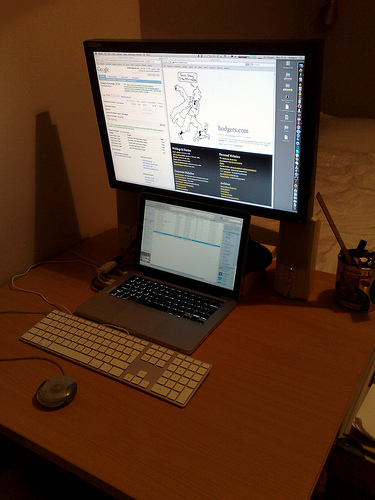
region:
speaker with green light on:
[274, 214, 320, 300]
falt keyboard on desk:
[20, 309, 212, 409]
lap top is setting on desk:
[77, 193, 251, 354]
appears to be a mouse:
[1, 355, 76, 410]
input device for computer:
[21, 306, 212, 406]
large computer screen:
[83, 38, 317, 219]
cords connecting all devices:
[91, 226, 141, 283]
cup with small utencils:
[315, 191, 373, 314]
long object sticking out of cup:
[313, 191, 355, 265]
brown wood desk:
[1, 225, 373, 498]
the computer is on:
[142, 77, 245, 149]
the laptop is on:
[157, 211, 208, 264]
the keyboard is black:
[134, 280, 195, 316]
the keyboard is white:
[70, 322, 132, 364]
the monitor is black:
[300, 60, 324, 155]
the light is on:
[282, 262, 294, 272]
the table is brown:
[262, 345, 300, 391]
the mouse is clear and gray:
[33, 367, 80, 409]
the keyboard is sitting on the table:
[165, 354, 213, 409]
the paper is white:
[349, 377, 374, 447]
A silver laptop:
[73, 189, 251, 354]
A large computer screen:
[82, 38, 326, 224]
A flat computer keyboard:
[18, 307, 213, 408]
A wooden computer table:
[0, 220, 374, 499]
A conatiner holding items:
[334, 248, 374, 312]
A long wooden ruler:
[316, 189, 352, 264]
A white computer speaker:
[271, 214, 321, 300]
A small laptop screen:
[132, 190, 249, 293]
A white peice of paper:
[351, 379, 374, 438]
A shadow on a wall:
[0, 109, 83, 268]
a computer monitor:
[81, 37, 323, 225]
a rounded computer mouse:
[0, 355, 78, 410]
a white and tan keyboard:
[17, 308, 212, 409]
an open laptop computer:
[73, 192, 252, 355]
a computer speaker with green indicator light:
[267, 214, 321, 303]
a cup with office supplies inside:
[314, 190, 374, 313]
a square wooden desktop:
[1, 220, 373, 498]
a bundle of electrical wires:
[7, 225, 139, 312]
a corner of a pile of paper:
[349, 381, 371, 435]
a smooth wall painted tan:
[1, 1, 142, 298]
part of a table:
[342, 412, 347, 416]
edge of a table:
[291, 439, 306, 461]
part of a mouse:
[56, 401, 66, 419]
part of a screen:
[217, 308, 220, 314]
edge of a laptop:
[194, 335, 198, 341]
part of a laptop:
[223, 291, 233, 308]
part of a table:
[147, 427, 157, 474]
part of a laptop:
[183, 338, 197, 346]